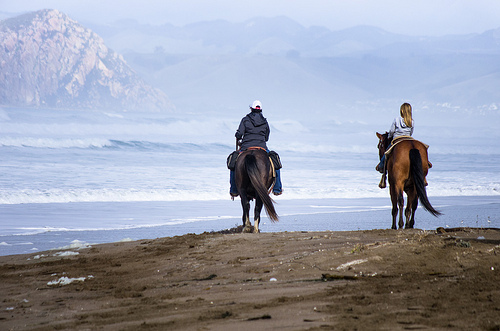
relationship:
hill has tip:
[2, 7, 169, 116] [36, 7, 67, 20]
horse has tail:
[231, 149, 282, 234] [244, 154, 279, 219]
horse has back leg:
[231, 149, 282, 234] [236, 165, 254, 234]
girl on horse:
[388, 99, 417, 141] [374, 130, 430, 232]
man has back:
[235, 101, 270, 150] [241, 113, 268, 140]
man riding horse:
[235, 101, 270, 150] [231, 149, 282, 234]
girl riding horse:
[388, 99, 417, 141] [374, 130, 430, 232]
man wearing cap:
[235, 101, 270, 150] [250, 101, 264, 112]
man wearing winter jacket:
[235, 101, 270, 150] [235, 113, 274, 149]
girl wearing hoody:
[388, 99, 417, 141] [387, 117, 418, 138]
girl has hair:
[388, 99, 417, 141] [397, 103, 415, 125]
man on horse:
[235, 101, 270, 150] [231, 149, 282, 234]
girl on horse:
[388, 99, 417, 141] [231, 149, 282, 234]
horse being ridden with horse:
[231, 149, 282, 234] [374, 130, 430, 232]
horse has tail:
[374, 130, 430, 232] [408, 145, 441, 216]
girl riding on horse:
[388, 99, 417, 141] [374, 130, 430, 232]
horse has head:
[374, 130, 430, 232] [374, 131, 392, 164]